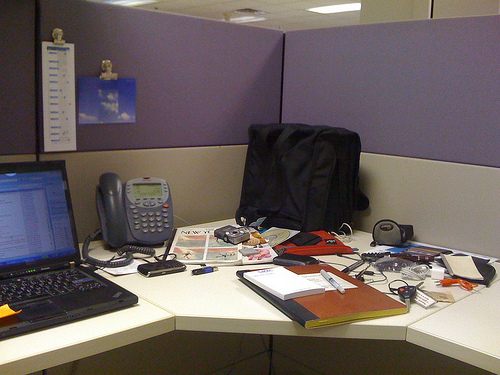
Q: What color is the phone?
A: Grey.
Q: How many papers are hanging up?
A: Two.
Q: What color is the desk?
A: White.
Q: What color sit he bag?
A: Black.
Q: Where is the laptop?
A: Next to the phone.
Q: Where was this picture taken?
A: An office.